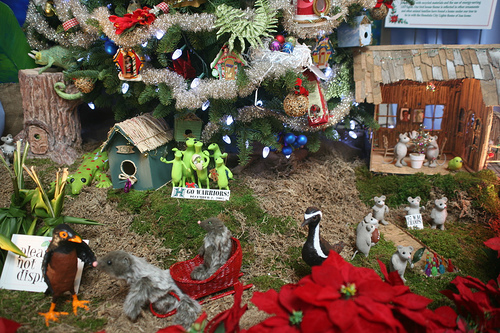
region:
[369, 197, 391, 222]
figurine on the turf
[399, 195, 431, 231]
figurine on the turf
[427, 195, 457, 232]
figurine on the turf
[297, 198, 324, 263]
figurine on the turf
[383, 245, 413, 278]
figurine on the turf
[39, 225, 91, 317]
figurine on the turf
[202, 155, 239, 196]
figurine on the turf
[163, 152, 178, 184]
figurine on the turf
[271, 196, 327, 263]
A skunk crawling under a poisettia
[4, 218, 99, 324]
A crow standing next to a white card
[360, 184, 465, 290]
A bunch of gray mice standing around a path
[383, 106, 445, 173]
Mice in a house with a flower pot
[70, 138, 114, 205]
A lizard with red spots next to a bird house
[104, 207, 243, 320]
Two furry creature with a red wicker sled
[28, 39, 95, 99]
A gecko on a log near the tree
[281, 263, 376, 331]
The poinsettia is red and yellow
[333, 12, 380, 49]
A small birdhouse hanging from the tree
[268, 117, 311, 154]
Blue balls hanging from the Christmas tree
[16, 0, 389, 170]
fake log under decorated Christmas tree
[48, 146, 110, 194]
green lizard figure with red spots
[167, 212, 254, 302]
grey stuffed animal in red wicker sleigh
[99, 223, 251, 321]
grey stuffed animal pulling red wicker sleigh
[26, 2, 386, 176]
decorated Christmas tree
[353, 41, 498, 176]
mice figures in miniature wood house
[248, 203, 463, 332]
black and white bird behind poinsettia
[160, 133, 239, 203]
"Go Warriors" sign under green animal figures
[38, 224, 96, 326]
bird figure with bright orange feet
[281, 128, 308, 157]
three round blue Christmas ornaments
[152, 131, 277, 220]
Group of frogs as an ornament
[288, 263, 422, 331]
Red poinsettia flowers in the grass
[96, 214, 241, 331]
Animal pulling a sled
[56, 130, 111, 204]
Lizard beside the birdhouse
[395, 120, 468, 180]
Mice on the front porch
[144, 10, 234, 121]
Christmas lights on the tree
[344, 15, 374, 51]
Small bird house on the tree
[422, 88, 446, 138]
Window on the house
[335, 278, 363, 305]
Center of the flower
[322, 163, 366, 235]
Dried straw on the ground